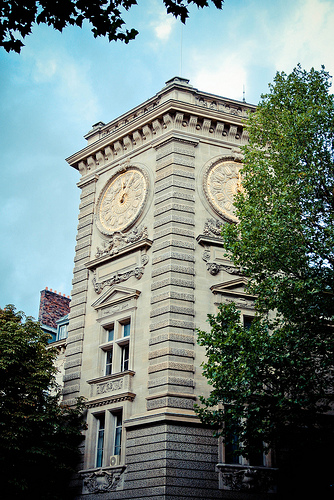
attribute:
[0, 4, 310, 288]
sky — Bright blue , high above.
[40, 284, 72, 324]
chimney — Stone 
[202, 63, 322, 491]
tree — Leafy green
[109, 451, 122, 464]
fan — Small 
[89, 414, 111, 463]
window — bottom 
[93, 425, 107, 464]
curtains — blue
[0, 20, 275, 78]
sky — blue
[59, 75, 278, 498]
building — stone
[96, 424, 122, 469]
window curtain — blue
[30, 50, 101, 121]
clouds — white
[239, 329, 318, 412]
leaves — green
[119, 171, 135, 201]
hands — gold